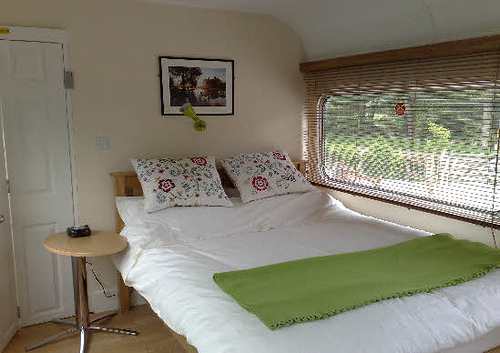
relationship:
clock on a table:
[65, 215, 93, 239] [33, 231, 139, 352]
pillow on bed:
[127, 152, 232, 212] [113, 155, 499, 351]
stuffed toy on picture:
[177, 101, 209, 131] [155, 52, 238, 117]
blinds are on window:
[300, 35, 498, 225] [302, 46, 497, 225]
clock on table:
[65, 215, 93, 239] [29, 235, 134, 347]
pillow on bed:
[217, 144, 305, 199] [113, 155, 499, 351]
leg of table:
[65, 254, 94, 332] [43, 214, 201, 288]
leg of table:
[65, 254, 94, 332] [29, 235, 134, 347]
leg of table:
[58, 275, 163, 332] [33, 214, 138, 258]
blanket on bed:
[196, 231, 498, 335] [132, 163, 481, 344]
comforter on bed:
[135, 197, 468, 341] [223, 256, 452, 326]